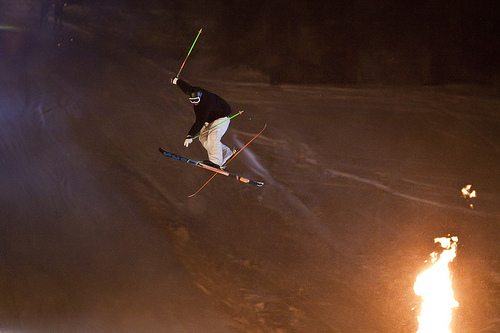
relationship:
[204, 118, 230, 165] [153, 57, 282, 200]
leg of man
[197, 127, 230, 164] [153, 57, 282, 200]
leg of man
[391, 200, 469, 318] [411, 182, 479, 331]
flame from fire